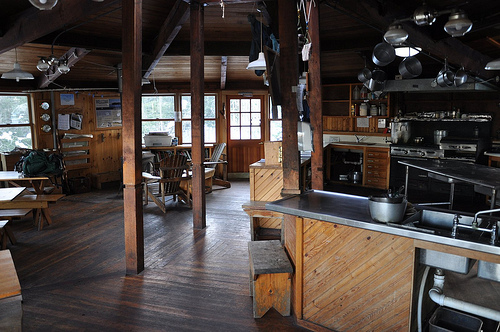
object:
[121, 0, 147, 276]
wood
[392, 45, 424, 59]
light fixture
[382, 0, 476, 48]
light fixture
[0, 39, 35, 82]
light fixture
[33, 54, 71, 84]
light fixture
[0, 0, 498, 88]
ceiling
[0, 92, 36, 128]
window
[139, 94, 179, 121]
window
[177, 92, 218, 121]
window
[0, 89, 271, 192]
front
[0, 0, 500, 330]
restaurant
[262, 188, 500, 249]
countertop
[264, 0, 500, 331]
kitchen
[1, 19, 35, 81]
lamp shade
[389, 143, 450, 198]
oven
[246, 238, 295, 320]
bench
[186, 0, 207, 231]
beam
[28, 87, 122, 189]
wall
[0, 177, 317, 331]
flooring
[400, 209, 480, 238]
sink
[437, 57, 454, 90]
pots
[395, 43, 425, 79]
pans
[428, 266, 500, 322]
tube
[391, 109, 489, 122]
stove top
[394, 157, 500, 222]
table